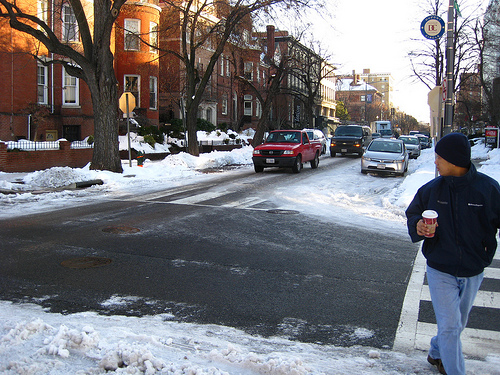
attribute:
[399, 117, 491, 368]
man — walking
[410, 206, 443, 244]
coffee — red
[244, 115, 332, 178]
truck — red, driving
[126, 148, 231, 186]
piles — snow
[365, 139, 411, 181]
car — silver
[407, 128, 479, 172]
cap — black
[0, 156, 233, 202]
snow — white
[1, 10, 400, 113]
homes — brick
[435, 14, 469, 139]
pole — gray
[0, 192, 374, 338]
road — gray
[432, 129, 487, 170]
hat — black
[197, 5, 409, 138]
buildings — brown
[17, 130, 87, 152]
fence — iron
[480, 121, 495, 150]
sign — red, blue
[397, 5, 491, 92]
trees — bare